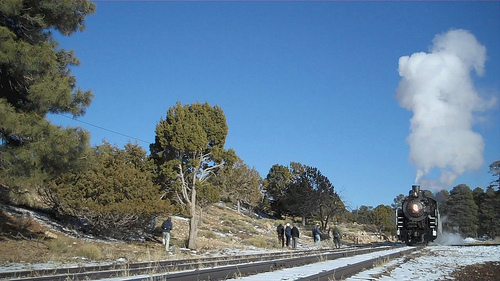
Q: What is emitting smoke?
A: A black locomotive.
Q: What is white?
A: Smoke.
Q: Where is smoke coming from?
A: The train.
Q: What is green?
A: Trees.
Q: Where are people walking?
A: Near the tracks.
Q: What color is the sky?
A: Blue.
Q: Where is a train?
A: On train tracks.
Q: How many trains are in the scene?
A: One.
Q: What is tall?
A: Trees.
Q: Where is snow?
A: On the ground.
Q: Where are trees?
A: In the distance.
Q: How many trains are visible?
A: 1.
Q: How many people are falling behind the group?
A: 1.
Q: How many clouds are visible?
A: 0.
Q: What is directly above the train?
A: Smoke.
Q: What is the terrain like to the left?
A: Sloped.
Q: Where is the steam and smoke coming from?
A: Train.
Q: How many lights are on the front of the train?
A: 1.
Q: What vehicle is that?
A: A train.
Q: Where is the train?
A: In the distance.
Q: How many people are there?
A: Five.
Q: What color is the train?
A: Black.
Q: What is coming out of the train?
A: Steam.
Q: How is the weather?
A: Sunny.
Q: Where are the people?
A: Near the train.